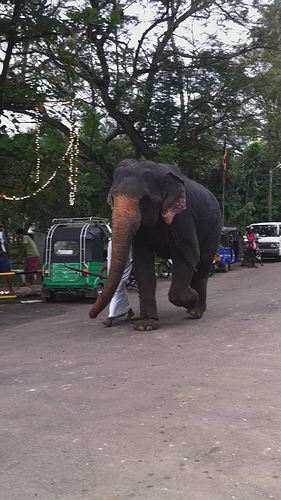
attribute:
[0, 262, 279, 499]
road — gray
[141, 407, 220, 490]
spots — white, brown, small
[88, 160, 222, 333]
elephant — walking, gray, big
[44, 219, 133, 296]
cars — parked, green, black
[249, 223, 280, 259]
cars — parked, white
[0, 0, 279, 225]
trees — green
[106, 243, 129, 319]
clothes — white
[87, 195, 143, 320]
trunk — brown, long, black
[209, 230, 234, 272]
vehicle — blue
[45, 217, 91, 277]
railing — silver